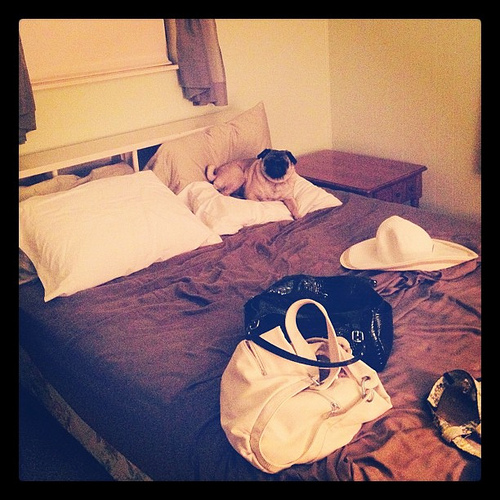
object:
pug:
[204, 148, 303, 220]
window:
[20, 16, 176, 83]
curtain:
[164, 16, 229, 106]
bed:
[20, 107, 481, 482]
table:
[294, 148, 426, 209]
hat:
[339, 213, 479, 271]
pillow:
[144, 101, 274, 193]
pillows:
[18, 168, 225, 301]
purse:
[243, 275, 396, 370]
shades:
[20, 20, 178, 92]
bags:
[220, 296, 393, 474]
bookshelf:
[18, 106, 248, 234]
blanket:
[18, 185, 482, 481]